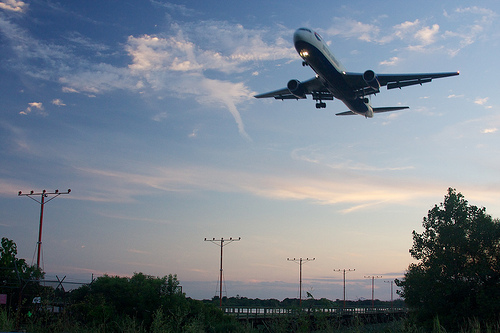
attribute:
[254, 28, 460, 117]
airplane — flying, large, white, in air, in flight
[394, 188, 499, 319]
tree — leafy, green, tall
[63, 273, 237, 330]
bushes — green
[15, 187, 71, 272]
pole — t-shaped, red, tall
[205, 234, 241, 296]
pole — t-shaped, red, for electricity, tall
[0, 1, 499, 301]
sky — sunlit, sparse of clouds, blue, cloudy, partly cloudy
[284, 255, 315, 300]
pole — t-shaped, red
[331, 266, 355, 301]
pole — t-shaped, tall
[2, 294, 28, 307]
train — here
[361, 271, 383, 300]
pole — tall, t-shaped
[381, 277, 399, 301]
pole — tall, t-shaped